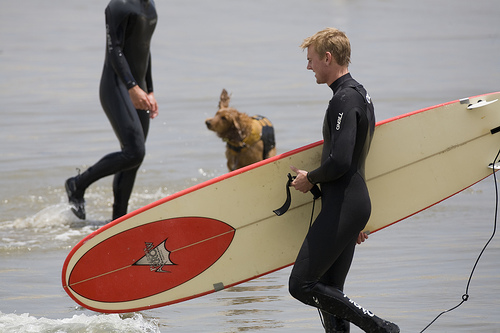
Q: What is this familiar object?
A: Surfboard.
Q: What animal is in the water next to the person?
A: Dog.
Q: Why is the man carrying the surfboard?
A: Preparing surf waves.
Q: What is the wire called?
A: Tether.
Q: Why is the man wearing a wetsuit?
A: Mainly warmth.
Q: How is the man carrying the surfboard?
A: Right arm over and under.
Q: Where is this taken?
A: A beach.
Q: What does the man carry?
A: A surfboard.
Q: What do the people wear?
A: Black wetsuits.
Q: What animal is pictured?
A: A dog.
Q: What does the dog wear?
A: A black life vest.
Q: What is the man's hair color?
A: Blonde.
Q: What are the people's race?
A: Caucasian.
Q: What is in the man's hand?
A: One end of the surfboard leash.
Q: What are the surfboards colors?
A: Red and white.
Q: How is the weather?
A: Sunny.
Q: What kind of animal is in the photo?
A: A dog.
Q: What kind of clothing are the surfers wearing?
A: Wetsuits.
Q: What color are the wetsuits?
A: Black.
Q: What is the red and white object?
A: Surf board.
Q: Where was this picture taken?
A: At the beach.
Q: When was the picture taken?
A: Daytime.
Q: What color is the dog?
A: Brown.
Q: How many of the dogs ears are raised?
A: One.